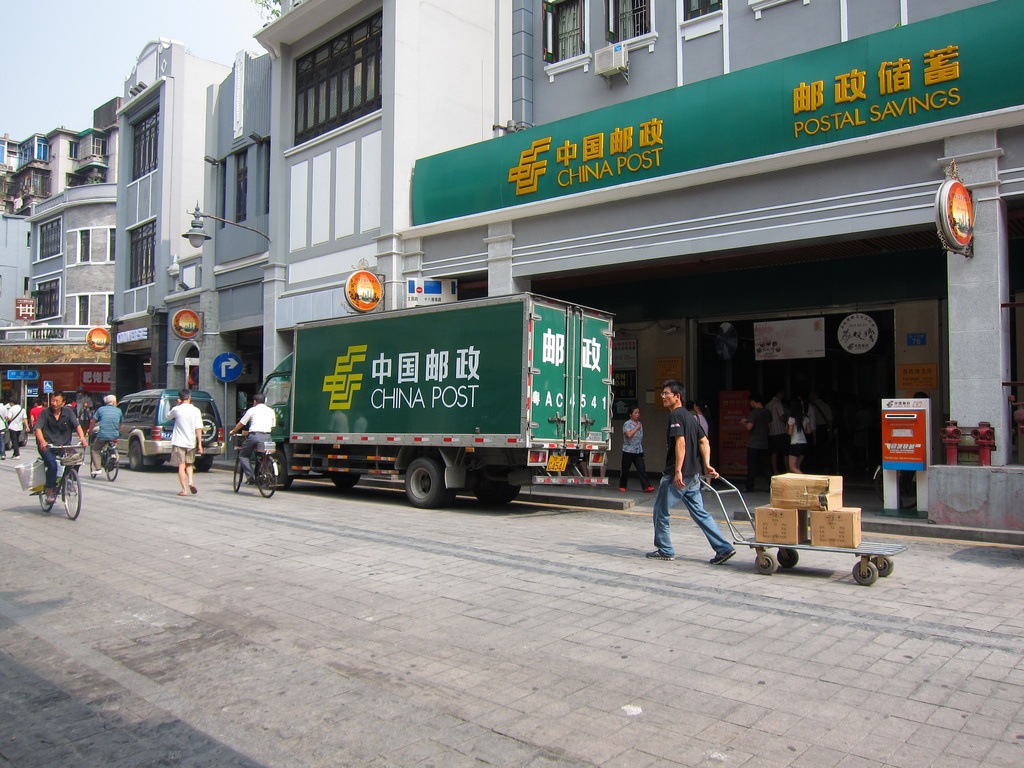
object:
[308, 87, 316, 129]
clean/clear glass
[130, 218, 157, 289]
glass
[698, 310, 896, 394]
glass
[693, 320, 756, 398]
glass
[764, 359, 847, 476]
glass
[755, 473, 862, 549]
boxes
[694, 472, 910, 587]
cart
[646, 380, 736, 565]
man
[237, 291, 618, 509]
truck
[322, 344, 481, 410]
graphics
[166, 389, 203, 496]
person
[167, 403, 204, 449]
t-shirt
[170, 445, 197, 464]
shorts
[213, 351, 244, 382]
turn sign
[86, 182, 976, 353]
signs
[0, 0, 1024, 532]
buildings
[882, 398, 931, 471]
box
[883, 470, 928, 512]
post